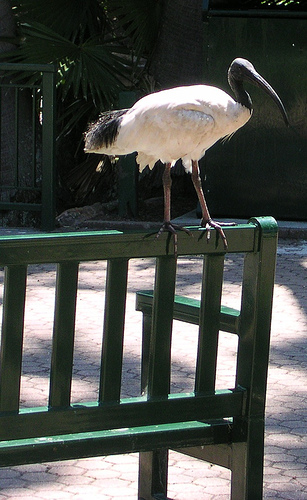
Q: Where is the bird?
A: Standing on top of a bench.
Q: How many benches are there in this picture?
A: One.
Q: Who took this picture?
A: A cameraman.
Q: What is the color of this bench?
A: Green.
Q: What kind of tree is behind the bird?
A: A palm tree.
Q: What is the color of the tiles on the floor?
A: Grey.